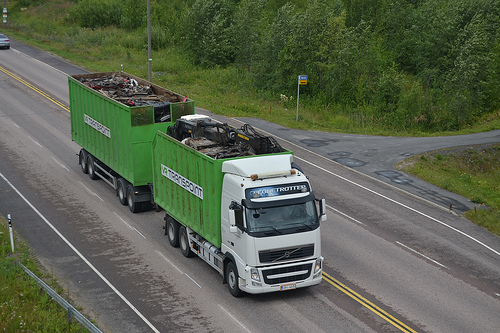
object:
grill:
[254, 243, 325, 263]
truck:
[145, 113, 330, 299]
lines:
[393, 240, 455, 273]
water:
[0, 138, 112, 257]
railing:
[14, 259, 106, 332]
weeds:
[0, 220, 96, 332]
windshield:
[247, 197, 318, 232]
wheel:
[177, 225, 197, 255]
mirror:
[318, 196, 329, 223]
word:
[161, 163, 203, 199]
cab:
[229, 183, 318, 238]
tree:
[376, 58, 411, 116]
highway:
[0, 32, 500, 332]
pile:
[178, 110, 254, 159]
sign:
[295, 75, 313, 85]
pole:
[295, 78, 302, 123]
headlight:
[249, 269, 262, 284]